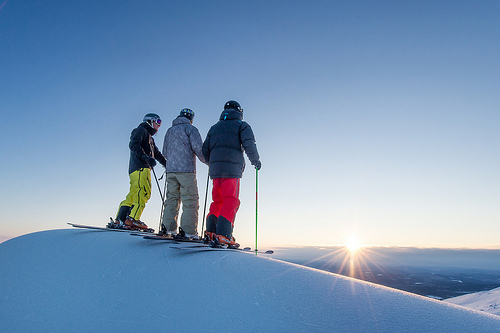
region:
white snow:
[85, 264, 162, 324]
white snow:
[135, 282, 219, 322]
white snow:
[61, 277, 186, 328]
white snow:
[78, 282, 142, 307]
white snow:
[111, 257, 239, 324]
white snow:
[110, 271, 195, 319]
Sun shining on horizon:
[335, 230, 382, 271]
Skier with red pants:
[206, 167, 241, 237]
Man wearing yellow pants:
[117, 170, 152, 227]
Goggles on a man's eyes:
[152, 115, 164, 125]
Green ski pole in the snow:
[249, 165, 261, 255]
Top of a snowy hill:
[11, 230, 489, 323]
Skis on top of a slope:
[130, 231, 284, 260]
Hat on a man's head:
[222, 99, 244, 108]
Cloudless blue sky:
[15, 7, 495, 79]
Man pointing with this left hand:
[154, 142, 174, 171]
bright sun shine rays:
[306, 198, 423, 284]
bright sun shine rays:
[323, 242, 376, 308]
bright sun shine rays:
[336, 233, 432, 320]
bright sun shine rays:
[343, 251, 379, 287]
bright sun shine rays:
[345, 181, 411, 291]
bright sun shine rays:
[306, 209, 383, 312]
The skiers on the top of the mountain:
[106, 85, 263, 253]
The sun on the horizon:
[278, 221, 400, 314]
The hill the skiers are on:
[2, 223, 499, 331]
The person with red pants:
[197, 96, 264, 251]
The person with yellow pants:
[110, 106, 166, 231]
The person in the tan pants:
[156, 104, 208, 244]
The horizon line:
[0, 224, 498, 258]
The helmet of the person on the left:
[141, 109, 161, 133]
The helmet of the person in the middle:
[170, 103, 200, 121]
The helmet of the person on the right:
[217, 97, 246, 122]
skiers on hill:
[76, 62, 306, 279]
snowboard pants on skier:
[202, 166, 257, 263]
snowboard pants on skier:
[153, 169, 199, 246]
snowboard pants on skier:
[109, 158, 149, 230]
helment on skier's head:
[217, 99, 249, 116]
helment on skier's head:
[172, 105, 197, 120]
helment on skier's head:
[137, 106, 161, 133]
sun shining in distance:
[298, 216, 394, 279]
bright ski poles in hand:
[242, 157, 271, 267]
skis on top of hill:
[57, 209, 119, 234]